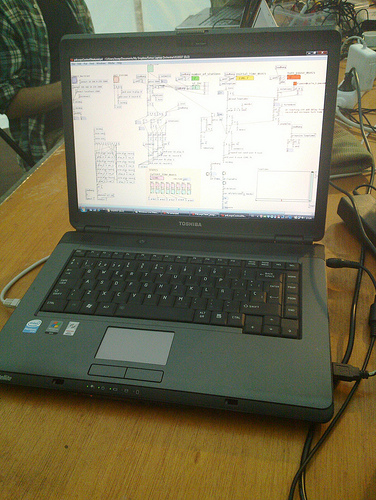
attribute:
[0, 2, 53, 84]
shirt — plaid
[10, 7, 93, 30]
shirt — open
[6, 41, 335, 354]
laptop — open, grey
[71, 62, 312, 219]
diagram — lifted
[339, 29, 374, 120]
powerstrip — white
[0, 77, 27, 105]
sleeve — rooled up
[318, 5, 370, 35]
wires — tangled up, black, tangled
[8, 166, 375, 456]
desk — wooden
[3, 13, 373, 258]
table — wooden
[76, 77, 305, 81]
boxes — colored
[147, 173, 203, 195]
bluepattern — repeated